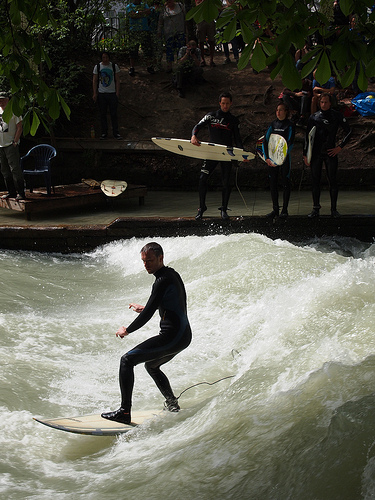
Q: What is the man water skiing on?
A: Surfboard.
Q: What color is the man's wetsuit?
A: Black.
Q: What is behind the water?
A: Trees.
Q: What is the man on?
A: Surf board.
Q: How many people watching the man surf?
A: Three.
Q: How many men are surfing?
A: One.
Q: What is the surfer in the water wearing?
A: Wetsuit.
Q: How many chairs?
A: One.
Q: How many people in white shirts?
A: Two.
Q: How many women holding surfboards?
A: One.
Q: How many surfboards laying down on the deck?
A: One.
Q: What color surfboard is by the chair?
A: White.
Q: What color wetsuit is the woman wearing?
A: Black and blue.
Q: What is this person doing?
A: Surfing.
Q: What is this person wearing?
A: Wetsuit.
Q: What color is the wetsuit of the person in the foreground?
A: Black.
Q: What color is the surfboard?
A: Tan and grey.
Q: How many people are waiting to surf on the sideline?
A: Three.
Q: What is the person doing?
A: Surfing.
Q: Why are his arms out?
A: For balance.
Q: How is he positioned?
A: He is balancing.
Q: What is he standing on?
A: A surfboard.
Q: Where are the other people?
A: On the ledge.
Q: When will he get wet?
A: When the water splashes.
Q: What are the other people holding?
A: Surfboards.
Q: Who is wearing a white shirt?
A: The man in the background.